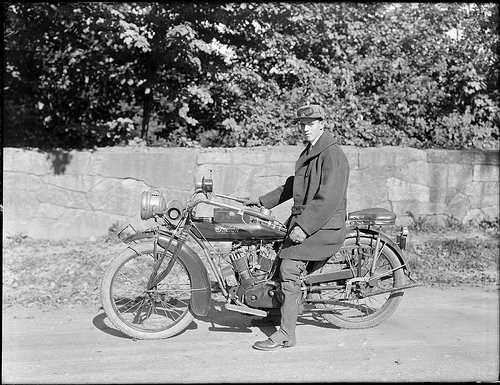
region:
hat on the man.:
[287, 101, 331, 147]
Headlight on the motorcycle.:
[135, 187, 170, 227]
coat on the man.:
[255, 100, 355, 272]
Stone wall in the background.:
[2, 140, 498, 242]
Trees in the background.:
[4, 3, 499, 150]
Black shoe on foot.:
[250, 334, 300, 349]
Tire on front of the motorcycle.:
[95, 232, 217, 341]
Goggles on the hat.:
[291, 103, 327, 120]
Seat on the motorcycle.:
[341, 196, 401, 229]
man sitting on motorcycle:
[94, 101, 425, 356]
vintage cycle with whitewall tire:
[95, 161, 426, 356]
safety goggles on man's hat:
[293, 102, 316, 122]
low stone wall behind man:
[4, 140, 498, 247]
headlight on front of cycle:
[135, 188, 167, 222]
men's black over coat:
[255, 127, 352, 269]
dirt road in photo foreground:
[5, 275, 498, 382]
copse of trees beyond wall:
[4, 5, 497, 165]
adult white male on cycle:
[236, 104, 356, 352]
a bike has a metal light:
[130, 186, 168, 220]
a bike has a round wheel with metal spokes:
[88, 227, 212, 347]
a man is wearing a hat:
[288, 100, 325, 124]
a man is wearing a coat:
[257, 136, 357, 264]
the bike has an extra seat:
[350, 202, 402, 232]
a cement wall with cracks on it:
[6, 142, 138, 243]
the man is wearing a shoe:
[247, 329, 297, 357]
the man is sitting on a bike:
[83, 91, 410, 367]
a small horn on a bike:
[191, 172, 213, 200]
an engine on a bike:
[210, 243, 277, 315]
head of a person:
[286, 84, 339, 150]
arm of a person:
[292, 159, 353, 236]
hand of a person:
[269, 225, 309, 261]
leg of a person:
[262, 255, 320, 331]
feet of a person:
[254, 330, 311, 353]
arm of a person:
[251, 178, 293, 217]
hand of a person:
[237, 189, 264, 214]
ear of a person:
[315, 111, 332, 128]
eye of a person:
[298, 118, 315, 128]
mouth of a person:
[300, 133, 319, 140]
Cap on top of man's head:
[292, 104, 328, 123]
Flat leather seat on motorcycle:
[347, 204, 395, 226]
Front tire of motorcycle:
[102, 245, 202, 337]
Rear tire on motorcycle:
[322, 240, 404, 326]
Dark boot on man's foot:
[257, 339, 295, 348]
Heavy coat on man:
[268, 140, 347, 260]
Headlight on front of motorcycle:
[137, 190, 164, 219]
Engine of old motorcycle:
[223, 239, 280, 301]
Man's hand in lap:
[290, 226, 306, 243]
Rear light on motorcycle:
[399, 224, 408, 241]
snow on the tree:
[442, 25, 459, 49]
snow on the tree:
[241, 113, 262, 133]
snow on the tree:
[91, 103, 131, 135]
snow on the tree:
[328, 3, 358, 40]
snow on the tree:
[36, 13, 154, 82]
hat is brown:
[290, 103, 327, 123]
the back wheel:
[301, 221, 409, 334]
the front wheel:
[79, 222, 201, 349]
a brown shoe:
[247, 329, 296, 356]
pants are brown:
[274, 253, 312, 337]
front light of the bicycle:
[135, 184, 172, 225]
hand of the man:
[288, 226, 305, 247]